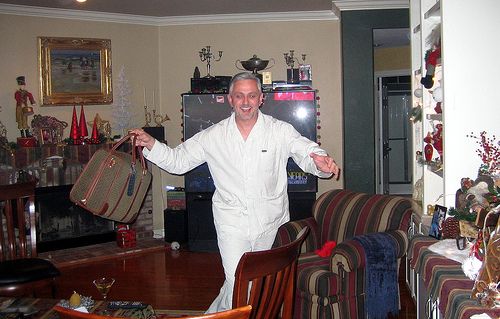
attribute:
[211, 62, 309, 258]
man — standing, looking, smiling, old, grey, laughing, close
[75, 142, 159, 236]
suitcase — brown, green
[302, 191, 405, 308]
chair — sitting, blue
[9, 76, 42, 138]
solider — red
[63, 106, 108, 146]
trees — green, red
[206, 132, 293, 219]
robe — white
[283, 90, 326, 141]
tv — close, on, big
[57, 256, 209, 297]
floor — wood